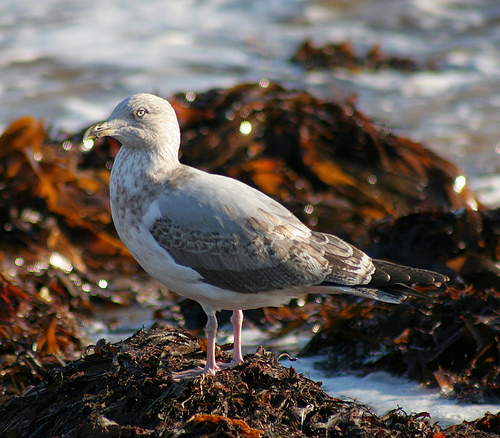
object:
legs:
[171, 308, 220, 382]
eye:
[136, 106, 146, 117]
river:
[4, 1, 499, 209]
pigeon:
[80, 91, 450, 384]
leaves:
[224, 116, 267, 151]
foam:
[279, 355, 496, 417]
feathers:
[108, 164, 451, 316]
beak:
[82, 121, 112, 141]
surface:
[6, 82, 454, 414]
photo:
[4, 4, 499, 436]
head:
[81, 91, 181, 151]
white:
[172, 272, 201, 300]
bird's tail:
[282, 229, 449, 308]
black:
[376, 257, 449, 296]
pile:
[193, 81, 413, 197]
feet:
[167, 362, 221, 383]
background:
[1, 1, 499, 438]